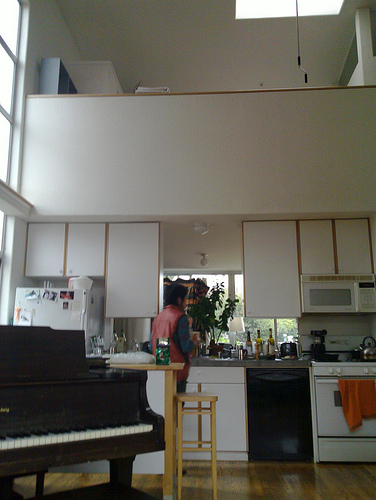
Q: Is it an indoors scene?
A: Yes, it is indoors.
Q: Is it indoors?
A: Yes, it is indoors.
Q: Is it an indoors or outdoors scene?
A: It is indoors.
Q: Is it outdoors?
A: No, it is indoors.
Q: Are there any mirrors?
A: No, there are no mirrors.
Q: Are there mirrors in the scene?
A: No, there are no mirrors.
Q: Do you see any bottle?
A: Yes, there is a bottle.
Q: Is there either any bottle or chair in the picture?
A: Yes, there is a bottle.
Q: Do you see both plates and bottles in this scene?
A: No, there is a bottle but no plates.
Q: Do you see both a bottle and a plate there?
A: No, there is a bottle but no plates.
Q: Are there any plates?
A: No, there are no plates.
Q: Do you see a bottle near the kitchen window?
A: Yes, there is a bottle near the window.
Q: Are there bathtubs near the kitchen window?
A: No, there is a bottle near the window.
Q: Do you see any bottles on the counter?
A: Yes, there is a bottle on the counter.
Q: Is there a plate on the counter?
A: No, there is a bottle on the counter.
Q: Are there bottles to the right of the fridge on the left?
A: Yes, there is a bottle to the right of the fridge.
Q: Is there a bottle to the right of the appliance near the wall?
A: Yes, there is a bottle to the right of the fridge.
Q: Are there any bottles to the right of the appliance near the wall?
A: Yes, there is a bottle to the right of the fridge.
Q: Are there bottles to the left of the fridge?
A: No, the bottle is to the right of the fridge.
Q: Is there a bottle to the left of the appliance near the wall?
A: No, the bottle is to the right of the fridge.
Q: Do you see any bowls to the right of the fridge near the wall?
A: No, there is a bottle to the right of the freezer.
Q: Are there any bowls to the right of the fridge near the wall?
A: No, there is a bottle to the right of the freezer.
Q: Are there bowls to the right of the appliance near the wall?
A: No, there is a bottle to the right of the freezer.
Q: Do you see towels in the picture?
A: Yes, there is a towel.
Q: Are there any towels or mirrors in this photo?
A: Yes, there is a towel.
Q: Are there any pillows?
A: No, there are no pillows.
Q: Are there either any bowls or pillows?
A: No, there are no pillows or bowls.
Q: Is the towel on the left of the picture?
A: No, the towel is on the right of the image.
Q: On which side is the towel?
A: The towel is on the right of the image.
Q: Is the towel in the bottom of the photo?
A: Yes, the towel is in the bottom of the image.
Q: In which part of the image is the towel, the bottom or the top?
A: The towel is in the bottom of the image.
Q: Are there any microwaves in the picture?
A: Yes, there is a microwave.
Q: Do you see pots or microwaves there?
A: Yes, there is a microwave.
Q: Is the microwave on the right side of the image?
A: Yes, the microwave is on the right of the image.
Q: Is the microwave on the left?
A: No, the microwave is on the right of the image.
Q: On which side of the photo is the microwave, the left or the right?
A: The microwave is on the right of the image.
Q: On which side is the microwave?
A: The microwave is on the right of the image.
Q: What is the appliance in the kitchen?
A: The appliance is a microwave.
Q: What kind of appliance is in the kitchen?
A: The appliance is a microwave.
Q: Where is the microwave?
A: The microwave is in the kitchen.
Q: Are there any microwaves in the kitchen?
A: Yes, there is a microwave in the kitchen.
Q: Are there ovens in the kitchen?
A: No, there is a microwave in the kitchen.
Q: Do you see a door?
A: Yes, there is a door.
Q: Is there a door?
A: Yes, there is a door.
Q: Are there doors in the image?
A: Yes, there is a door.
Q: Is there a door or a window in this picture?
A: Yes, there is a door.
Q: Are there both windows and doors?
A: Yes, there are both a door and windows.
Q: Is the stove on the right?
A: Yes, the stove is on the right of the image.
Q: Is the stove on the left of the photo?
A: No, the stove is on the right of the image.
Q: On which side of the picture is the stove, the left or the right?
A: The stove is on the right of the image.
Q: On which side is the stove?
A: The stove is on the right of the image.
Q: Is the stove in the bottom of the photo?
A: Yes, the stove is in the bottom of the image.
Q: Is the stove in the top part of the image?
A: No, the stove is in the bottom of the image.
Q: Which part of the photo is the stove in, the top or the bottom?
A: The stove is in the bottom of the image.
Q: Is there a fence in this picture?
A: No, there are no fences.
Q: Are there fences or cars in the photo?
A: No, there are no fences or cars.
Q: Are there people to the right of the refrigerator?
A: Yes, there is a person to the right of the refrigerator.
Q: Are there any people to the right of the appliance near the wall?
A: Yes, there is a person to the right of the refrigerator.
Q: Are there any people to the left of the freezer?
A: No, the person is to the right of the freezer.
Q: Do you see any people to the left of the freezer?
A: No, the person is to the right of the freezer.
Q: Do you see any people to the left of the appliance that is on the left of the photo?
A: No, the person is to the right of the freezer.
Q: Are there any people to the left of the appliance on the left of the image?
A: No, the person is to the right of the freezer.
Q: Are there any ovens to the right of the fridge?
A: No, there is a person to the right of the fridge.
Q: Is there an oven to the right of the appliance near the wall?
A: No, there is a person to the right of the fridge.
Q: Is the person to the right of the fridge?
A: Yes, the person is to the right of the fridge.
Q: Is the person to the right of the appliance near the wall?
A: Yes, the person is to the right of the fridge.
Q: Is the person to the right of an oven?
A: No, the person is to the right of the fridge.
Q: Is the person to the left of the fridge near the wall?
A: No, the person is to the right of the freezer.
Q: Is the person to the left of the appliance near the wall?
A: No, the person is to the right of the freezer.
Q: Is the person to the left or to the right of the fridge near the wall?
A: The person is to the right of the freezer.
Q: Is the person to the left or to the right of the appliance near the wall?
A: The person is to the right of the freezer.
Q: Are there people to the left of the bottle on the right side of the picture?
A: Yes, there is a person to the left of the bottle.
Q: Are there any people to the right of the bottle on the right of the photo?
A: No, the person is to the left of the bottle.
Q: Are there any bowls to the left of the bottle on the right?
A: No, there is a person to the left of the bottle.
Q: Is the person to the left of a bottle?
A: Yes, the person is to the left of a bottle.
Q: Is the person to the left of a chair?
A: No, the person is to the left of a bottle.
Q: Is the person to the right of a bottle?
A: No, the person is to the left of a bottle.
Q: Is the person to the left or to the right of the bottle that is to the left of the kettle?
A: The person is to the left of the bottle.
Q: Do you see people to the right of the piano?
A: Yes, there is a person to the right of the piano.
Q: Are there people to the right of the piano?
A: Yes, there is a person to the right of the piano.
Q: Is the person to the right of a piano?
A: Yes, the person is to the right of a piano.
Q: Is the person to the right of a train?
A: No, the person is to the right of a piano.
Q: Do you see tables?
A: Yes, there is a table.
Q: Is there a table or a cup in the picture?
A: Yes, there is a table.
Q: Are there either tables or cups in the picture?
A: Yes, there is a table.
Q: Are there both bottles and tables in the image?
A: Yes, there are both a table and a bottle.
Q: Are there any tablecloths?
A: No, there are no tablecloths.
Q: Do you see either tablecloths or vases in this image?
A: No, there are no tablecloths or vases.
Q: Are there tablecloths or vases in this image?
A: No, there are no tablecloths or vases.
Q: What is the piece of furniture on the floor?
A: The piece of furniture is a table.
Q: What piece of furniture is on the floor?
A: The piece of furniture is a table.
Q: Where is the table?
A: The table is on the floor.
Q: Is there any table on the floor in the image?
A: Yes, there is a table on the floor.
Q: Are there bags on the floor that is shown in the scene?
A: No, there is a table on the floor.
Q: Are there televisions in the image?
A: No, there are no televisions.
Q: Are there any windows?
A: Yes, there is a window.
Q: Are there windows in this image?
A: Yes, there is a window.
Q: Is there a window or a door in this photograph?
A: Yes, there is a window.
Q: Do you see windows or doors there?
A: Yes, there is a window.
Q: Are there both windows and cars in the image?
A: No, there is a window but no cars.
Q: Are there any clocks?
A: No, there are no clocks.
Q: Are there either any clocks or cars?
A: No, there are no clocks or cars.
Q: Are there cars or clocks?
A: No, there are no clocks or cars.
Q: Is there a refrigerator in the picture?
A: Yes, there is a refrigerator.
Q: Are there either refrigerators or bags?
A: Yes, there is a refrigerator.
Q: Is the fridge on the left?
A: Yes, the fridge is on the left of the image.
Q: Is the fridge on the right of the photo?
A: No, the fridge is on the left of the image.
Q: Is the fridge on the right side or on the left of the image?
A: The fridge is on the left of the image.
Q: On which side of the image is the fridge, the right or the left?
A: The fridge is on the left of the image.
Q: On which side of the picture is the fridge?
A: The fridge is on the left of the image.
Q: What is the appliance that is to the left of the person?
A: The appliance is a refrigerator.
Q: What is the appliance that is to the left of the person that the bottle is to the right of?
A: The appliance is a refrigerator.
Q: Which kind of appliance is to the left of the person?
A: The appliance is a refrigerator.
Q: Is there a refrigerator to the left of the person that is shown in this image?
A: Yes, there is a refrigerator to the left of the person.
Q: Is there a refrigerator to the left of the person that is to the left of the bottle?
A: Yes, there is a refrigerator to the left of the person.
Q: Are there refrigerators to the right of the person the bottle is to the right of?
A: No, the refrigerator is to the left of the person.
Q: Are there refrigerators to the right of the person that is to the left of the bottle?
A: No, the refrigerator is to the left of the person.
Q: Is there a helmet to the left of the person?
A: No, there is a refrigerator to the left of the person.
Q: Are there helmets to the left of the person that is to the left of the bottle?
A: No, there is a refrigerator to the left of the person.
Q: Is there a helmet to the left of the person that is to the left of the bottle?
A: No, there is a refrigerator to the left of the person.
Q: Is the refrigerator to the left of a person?
A: Yes, the refrigerator is to the left of a person.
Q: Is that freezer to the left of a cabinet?
A: No, the freezer is to the left of a person.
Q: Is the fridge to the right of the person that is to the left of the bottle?
A: No, the fridge is to the left of the person.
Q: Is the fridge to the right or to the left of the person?
A: The fridge is to the left of the person.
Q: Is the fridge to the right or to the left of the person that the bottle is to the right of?
A: The fridge is to the left of the person.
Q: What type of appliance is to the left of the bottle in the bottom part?
A: The appliance is a refrigerator.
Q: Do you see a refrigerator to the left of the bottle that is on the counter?
A: Yes, there is a refrigerator to the left of the bottle.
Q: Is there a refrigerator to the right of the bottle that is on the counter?
A: No, the refrigerator is to the left of the bottle.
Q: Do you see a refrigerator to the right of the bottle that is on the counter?
A: No, the refrigerator is to the left of the bottle.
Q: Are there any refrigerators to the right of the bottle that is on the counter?
A: No, the refrigerator is to the left of the bottle.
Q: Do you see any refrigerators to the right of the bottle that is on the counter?
A: No, the refrigerator is to the left of the bottle.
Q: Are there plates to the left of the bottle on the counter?
A: No, there is a refrigerator to the left of the bottle.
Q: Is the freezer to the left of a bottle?
A: Yes, the freezer is to the left of a bottle.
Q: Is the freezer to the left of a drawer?
A: No, the freezer is to the left of a bottle.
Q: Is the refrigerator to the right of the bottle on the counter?
A: No, the refrigerator is to the left of the bottle.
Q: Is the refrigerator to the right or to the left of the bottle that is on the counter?
A: The refrigerator is to the left of the bottle.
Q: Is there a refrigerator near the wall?
A: Yes, there is a refrigerator near the wall.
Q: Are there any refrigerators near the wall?
A: Yes, there is a refrigerator near the wall.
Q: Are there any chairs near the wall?
A: No, there is a refrigerator near the wall.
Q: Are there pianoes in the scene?
A: Yes, there is a piano.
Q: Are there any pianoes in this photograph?
A: Yes, there is a piano.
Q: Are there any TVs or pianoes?
A: Yes, there is a piano.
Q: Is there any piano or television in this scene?
A: Yes, there is a piano.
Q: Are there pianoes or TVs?
A: Yes, there is a piano.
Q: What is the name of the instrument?
A: The instrument is a piano.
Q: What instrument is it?
A: The instrument is a piano.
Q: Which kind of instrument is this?
A: That is a piano.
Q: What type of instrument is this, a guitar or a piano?
A: That is a piano.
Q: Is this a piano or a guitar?
A: This is a piano.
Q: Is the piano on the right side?
A: No, the piano is on the left of the image.